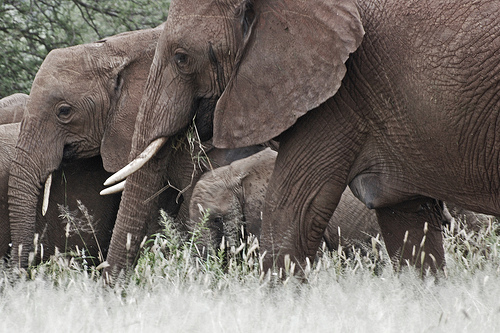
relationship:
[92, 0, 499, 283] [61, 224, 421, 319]
elephant eating hay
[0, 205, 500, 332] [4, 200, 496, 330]
field of grass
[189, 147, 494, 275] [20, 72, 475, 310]
baby elephant grazing in field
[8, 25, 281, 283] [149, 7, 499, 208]
elephant with mom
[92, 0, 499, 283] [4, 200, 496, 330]
elephant in grass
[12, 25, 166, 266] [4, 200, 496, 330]
elephant in grass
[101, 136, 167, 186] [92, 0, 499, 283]
tusks on elephant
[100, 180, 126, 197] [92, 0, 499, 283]
tusks on elephant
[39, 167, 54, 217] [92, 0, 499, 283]
tusks on elephant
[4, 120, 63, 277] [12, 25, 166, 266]
trunk of elephant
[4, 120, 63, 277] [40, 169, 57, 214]
trunk with tusk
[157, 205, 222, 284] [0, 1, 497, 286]
grass with elephants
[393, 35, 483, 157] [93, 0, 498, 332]
skin of elephant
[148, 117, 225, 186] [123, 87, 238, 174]
grass in mouth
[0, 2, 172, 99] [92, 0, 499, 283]
trees growing behind elephant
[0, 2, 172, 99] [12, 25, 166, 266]
trees growing behind elephant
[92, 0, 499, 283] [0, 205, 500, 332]
elephant walking in field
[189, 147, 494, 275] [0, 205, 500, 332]
baby elephant walking in field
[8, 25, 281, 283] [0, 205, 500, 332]
elephant walking in field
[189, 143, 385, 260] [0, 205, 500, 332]
baby elephant walking in field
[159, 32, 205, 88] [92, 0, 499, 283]
eye of elephant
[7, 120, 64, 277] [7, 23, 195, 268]
trunk of elephant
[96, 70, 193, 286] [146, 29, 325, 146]
trunk of elephant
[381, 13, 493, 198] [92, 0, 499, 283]
skin elephant of elephant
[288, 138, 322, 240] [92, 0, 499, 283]
skin elephant of elephant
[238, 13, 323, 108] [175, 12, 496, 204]
ear of elephant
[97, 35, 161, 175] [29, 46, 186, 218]
ear of elephant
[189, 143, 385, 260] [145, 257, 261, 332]
baby elephant in grass